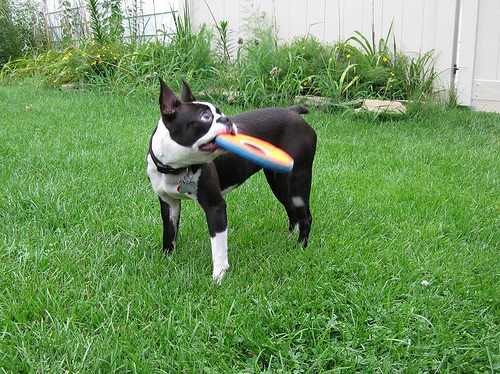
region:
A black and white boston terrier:
[141, 74, 319, 283]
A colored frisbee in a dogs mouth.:
[216, 134, 293, 174]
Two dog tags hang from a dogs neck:
[174, 177, 197, 197]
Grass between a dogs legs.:
[234, 215, 286, 279]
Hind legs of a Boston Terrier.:
[265, 171, 317, 252]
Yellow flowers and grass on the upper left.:
[60, 37, 122, 81]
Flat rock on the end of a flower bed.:
[357, 95, 409, 119]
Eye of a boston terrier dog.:
[196, 109, 210, 120]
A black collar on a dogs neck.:
[146, 141, 201, 180]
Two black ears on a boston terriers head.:
[152, 78, 197, 114]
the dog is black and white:
[212, 255, 224, 278]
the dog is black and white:
[210, 245, 219, 270]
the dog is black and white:
[216, 252, 224, 259]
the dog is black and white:
[213, 251, 220, 258]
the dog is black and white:
[219, 238, 227, 253]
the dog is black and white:
[213, 251, 221, 266]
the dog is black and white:
[207, 248, 222, 265]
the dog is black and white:
[214, 241, 223, 256]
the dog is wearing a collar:
[146, 145, 186, 186]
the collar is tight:
[143, 122, 165, 182]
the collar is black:
[146, 137, 171, 182]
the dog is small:
[126, 70, 334, 285]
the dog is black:
[139, 69, 332, 281]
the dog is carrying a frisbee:
[216, 123, 308, 183]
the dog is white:
[133, 74, 332, 285]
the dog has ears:
[143, 77, 209, 107]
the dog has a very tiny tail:
[286, 99, 314, 118]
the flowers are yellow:
[84, 47, 118, 70]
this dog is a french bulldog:
[97, 40, 448, 329]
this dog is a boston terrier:
[108, 32, 445, 314]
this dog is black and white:
[115, 60, 424, 305]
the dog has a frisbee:
[106, 56, 486, 318]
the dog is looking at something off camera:
[114, 52, 458, 340]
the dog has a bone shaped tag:
[97, 30, 424, 310]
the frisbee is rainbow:
[83, 60, 330, 267]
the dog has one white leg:
[115, 47, 370, 299]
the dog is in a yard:
[121, 43, 433, 315]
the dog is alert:
[114, 56, 458, 343]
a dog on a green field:
[130, 68, 331, 289]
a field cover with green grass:
[10, 70, 495, 365]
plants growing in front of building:
[20, 5, 425, 90]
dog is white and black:
[127, 60, 337, 286]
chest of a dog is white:
[148, 150, 201, 208]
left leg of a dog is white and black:
[197, 193, 242, 297]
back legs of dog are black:
[274, 188, 318, 261]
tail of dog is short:
[285, 94, 318, 123]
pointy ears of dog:
[149, 69, 199, 114]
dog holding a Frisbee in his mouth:
[124, 61, 336, 288]